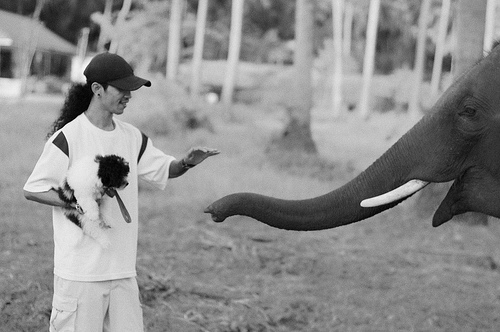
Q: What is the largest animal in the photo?
A: Elephant.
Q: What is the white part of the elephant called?
A: Tusks.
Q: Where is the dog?
A: Man's right hand.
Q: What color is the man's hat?
A: Black.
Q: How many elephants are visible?
A: One.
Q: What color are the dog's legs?
A: White.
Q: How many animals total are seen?
A: Two.